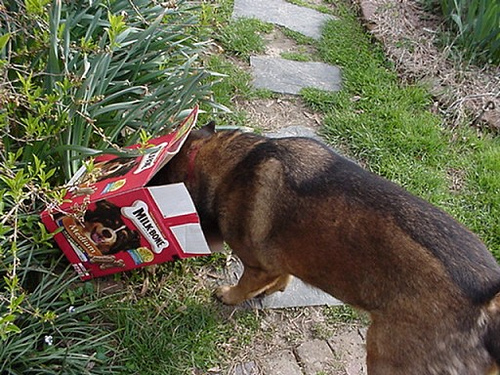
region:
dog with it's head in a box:
[34, 90, 486, 373]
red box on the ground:
[33, 97, 228, 294]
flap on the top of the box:
[138, 175, 219, 270]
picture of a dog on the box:
[56, 201, 145, 264]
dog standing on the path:
[153, 113, 493, 374]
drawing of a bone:
[121, 198, 173, 258]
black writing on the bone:
[118, 199, 170, 253]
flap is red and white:
[143, 180, 218, 273]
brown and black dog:
[157, 109, 497, 374]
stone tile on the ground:
[243, 48, 346, 106]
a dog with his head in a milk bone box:
[42, 98, 497, 368]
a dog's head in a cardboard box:
[71, 87, 243, 270]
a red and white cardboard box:
[41, 130, 206, 290]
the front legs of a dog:
[211, 251, 292, 328]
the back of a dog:
[263, 130, 488, 269]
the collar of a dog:
[178, 131, 201, 187]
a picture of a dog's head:
[83, 203, 130, 254]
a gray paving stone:
[248, 48, 350, 105]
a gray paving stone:
[230, 0, 340, 37]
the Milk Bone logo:
[123, 202, 168, 257]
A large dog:
[188, 113, 495, 363]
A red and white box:
[44, 153, 206, 283]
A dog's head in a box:
[33, 103, 478, 358]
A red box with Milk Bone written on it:
[61, 150, 182, 272]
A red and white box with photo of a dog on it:
[39, 146, 180, 291]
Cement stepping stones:
[244, 63, 354, 110]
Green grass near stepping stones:
[371, 73, 450, 163]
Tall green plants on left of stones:
[47, 70, 154, 112]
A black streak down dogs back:
[280, 140, 490, 296]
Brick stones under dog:
[268, 315, 338, 374]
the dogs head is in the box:
[157, 136, 226, 189]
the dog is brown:
[330, 239, 370, 268]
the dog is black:
[391, 195, 421, 225]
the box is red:
[126, 171, 144, 189]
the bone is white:
[124, 201, 157, 235]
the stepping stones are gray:
[281, 65, 306, 86]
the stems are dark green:
[102, 72, 140, 108]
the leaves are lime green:
[23, 105, 58, 136]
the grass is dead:
[380, 6, 415, 31]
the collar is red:
[182, 152, 199, 174]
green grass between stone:
[341, 37, 378, 94]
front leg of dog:
[214, 271, 291, 307]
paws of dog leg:
[216, 285, 236, 305]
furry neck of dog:
[198, 135, 274, 176]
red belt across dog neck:
[185, 142, 200, 174]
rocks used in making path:
[246, 51, 339, 101]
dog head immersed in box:
[58, 141, 198, 279]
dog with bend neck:
[171, 125, 246, 230]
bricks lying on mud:
[293, 335, 363, 373]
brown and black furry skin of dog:
[270, 161, 349, 271]